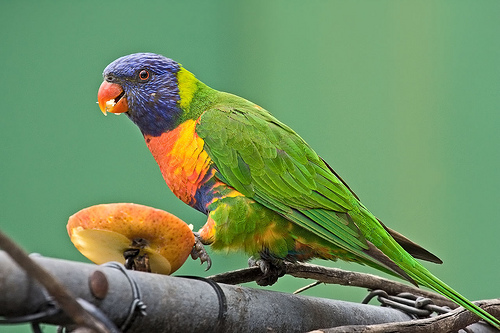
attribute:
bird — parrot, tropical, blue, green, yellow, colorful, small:
[94, 42, 497, 326]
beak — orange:
[94, 81, 129, 116]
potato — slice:
[64, 201, 197, 271]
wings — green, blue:
[198, 80, 498, 327]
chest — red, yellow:
[140, 119, 219, 205]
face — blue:
[105, 52, 185, 138]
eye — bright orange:
[135, 68, 152, 83]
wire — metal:
[104, 258, 152, 332]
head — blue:
[92, 50, 199, 137]